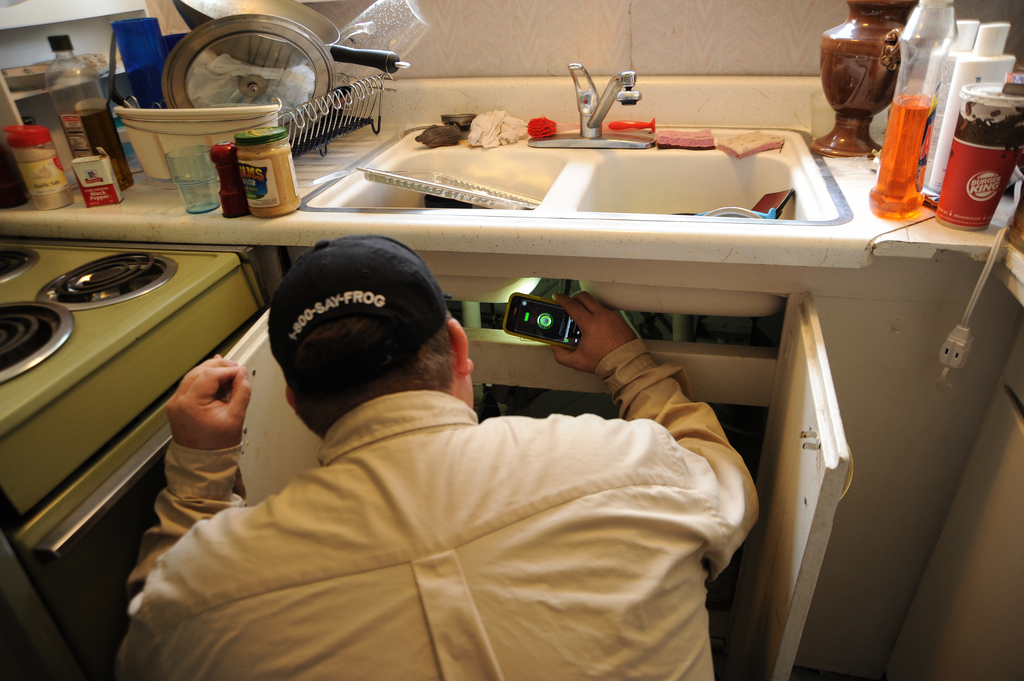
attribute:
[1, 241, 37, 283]
burner — black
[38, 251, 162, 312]
burner — black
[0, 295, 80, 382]
burner — black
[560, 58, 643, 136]
sink spout — silver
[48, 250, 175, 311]
stove burner — electric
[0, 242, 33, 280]
stove burner — electric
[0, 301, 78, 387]
stove burner — electric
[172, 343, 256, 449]
hand — chubby, male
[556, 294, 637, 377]
hand — chubby, male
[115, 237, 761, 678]
man — wearing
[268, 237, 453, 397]
black cap — worn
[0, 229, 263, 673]
green stove — old 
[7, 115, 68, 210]
spice container — plastic 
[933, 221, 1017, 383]
extension cord — White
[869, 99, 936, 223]
dish soap — orange 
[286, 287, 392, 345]
numbers letters — white